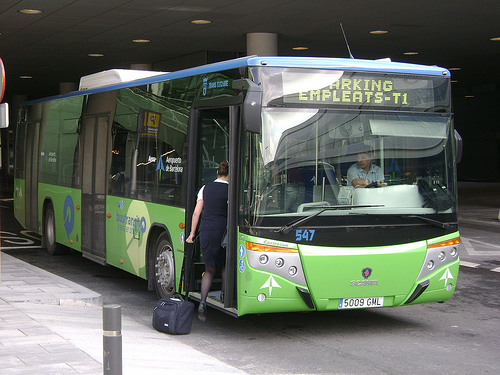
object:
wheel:
[152, 230, 175, 301]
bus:
[12, 23, 463, 318]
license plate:
[338, 297, 385, 309]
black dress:
[197, 179, 229, 269]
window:
[240, 72, 459, 226]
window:
[135, 107, 193, 208]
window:
[58, 134, 81, 189]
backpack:
[417, 176, 456, 214]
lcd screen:
[299, 77, 409, 105]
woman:
[185, 160, 229, 321]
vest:
[199, 181, 230, 232]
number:
[296, 229, 316, 241]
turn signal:
[245, 241, 298, 253]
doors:
[75, 111, 112, 265]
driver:
[347, 145, 388, 188]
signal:
[427, 236, 460, 249]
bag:
[152, 294, 196, 335]